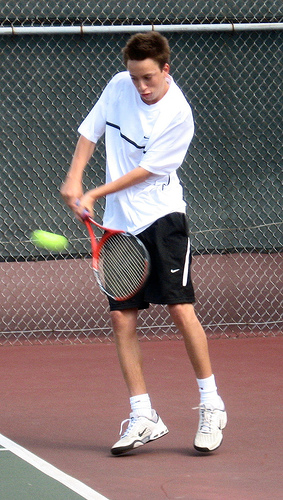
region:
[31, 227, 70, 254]
green tennis ball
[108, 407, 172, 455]
white tennis shoe with a check on it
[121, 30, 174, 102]
head of a man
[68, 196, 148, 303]
tennis racket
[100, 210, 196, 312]
black athletic shorts with a white check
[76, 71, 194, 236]
white shirt for male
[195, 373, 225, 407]
a white sock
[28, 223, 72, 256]
yellow tennis ball in the air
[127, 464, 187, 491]
clay on the court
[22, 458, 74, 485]
bold white line on the court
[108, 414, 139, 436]
white laces on sneakers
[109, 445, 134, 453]
black edge on white sneakers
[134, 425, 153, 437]
Nike swoosh on side of sneakers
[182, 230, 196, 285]
white line on side of shorts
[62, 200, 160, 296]
red and blue tennis racket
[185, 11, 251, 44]
silver pole on side of mesh fence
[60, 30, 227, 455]
Male tennis player swinging at ball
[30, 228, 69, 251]
Blurred image of yellow tennis ball in flight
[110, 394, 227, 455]
White Nike tennis shoes with black trim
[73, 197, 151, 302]
Red and black tennis racket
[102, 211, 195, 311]
Black shorts with white Nike swoosh and stripe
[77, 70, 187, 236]
Short sleeved white shirt with black stripe across chest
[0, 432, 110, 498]
White line on border of tennis court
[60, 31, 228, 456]
Man in short pants hitting tennis ball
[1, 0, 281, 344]
Tall metal mesh fence bordering tennis court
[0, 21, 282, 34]
Horizontal metal pipe supporting top of fence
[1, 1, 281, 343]
pole and chain link fence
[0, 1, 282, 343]
geen fabric behind fence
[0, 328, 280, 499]
red and green court surface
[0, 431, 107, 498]
white line on court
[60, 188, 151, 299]
two hands on racket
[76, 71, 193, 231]
shirt with horizontal stripe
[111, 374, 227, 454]
white socks and sneakers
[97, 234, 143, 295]
string of tennis racket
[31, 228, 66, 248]
blur of yellow tennis ball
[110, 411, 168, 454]
side of white sneaker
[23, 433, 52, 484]
white line on the court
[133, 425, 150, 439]
black check mark on the shoe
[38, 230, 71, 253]
a yellow tennis ball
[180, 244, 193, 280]
white stripe on black shorts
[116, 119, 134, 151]
black stripe on a white shirt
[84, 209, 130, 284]
a red tennis racket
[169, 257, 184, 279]
white check mark on the shorts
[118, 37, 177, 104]
hair on a mans head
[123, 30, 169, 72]
brown spiky hair on a boy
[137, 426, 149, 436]
a black nike swoosh symbol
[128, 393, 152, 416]
a white scrunched up sock